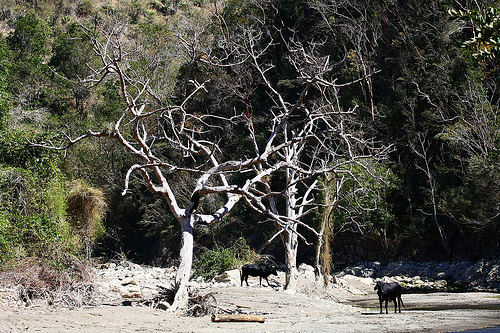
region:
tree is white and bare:
[54, 48, 339, 294]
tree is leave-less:
[38, 34, 333, 331]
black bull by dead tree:
[229, 253, 280, 288]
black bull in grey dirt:
[355, 277, 415, 327]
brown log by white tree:
[203, 319, 302, 323]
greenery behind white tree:
[3, 64, 163, 270]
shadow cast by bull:
[352, 300, 388, 319]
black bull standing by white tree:
[220, 271, 289, 281]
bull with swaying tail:
[367, 274, 419, 313]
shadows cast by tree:
[61, 211, 249, 318]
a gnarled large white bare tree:
[25, 23, 305, 310]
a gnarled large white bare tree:
[178, 21, 375, 286]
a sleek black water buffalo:
[372, 276, 404, 309]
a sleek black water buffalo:
[239, 256, 275, 286]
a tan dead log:
[210, 313, 266, 321]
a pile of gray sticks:
[15, 246, 93, 307]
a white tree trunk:
[172, 221, 195, 315]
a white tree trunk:
[281, 183, 299, 290]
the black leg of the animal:
[378, 298, 383, 313]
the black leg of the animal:
[382, 298, 389, 313]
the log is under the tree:
[175, 308, 293, 320]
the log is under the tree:
[199, 304, 283, 331]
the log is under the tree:
[220, 310, 275, 325]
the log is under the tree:
[196, 282, 258, 330]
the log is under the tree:
[166, 314, 286, 326]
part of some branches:
[258, 50, 300, 120]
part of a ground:
[306, 285, 353, 326]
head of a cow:
[366, 266, 386, 299]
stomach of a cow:
[386, 277, 403, 298]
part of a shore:
[437, 292, 461, 318]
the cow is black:
[333, 260, 452, 325]